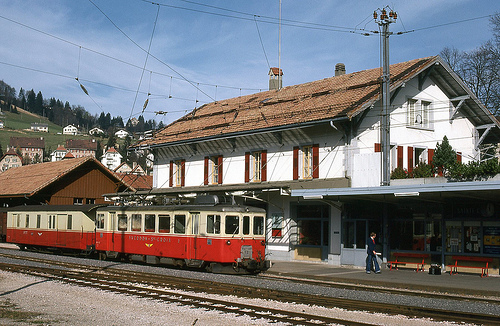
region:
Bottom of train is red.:
[82, 222, 287, 324]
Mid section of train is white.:
[25, 205, 229, 233]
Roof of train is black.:
[68, 200, 260, 223]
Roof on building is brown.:
[224, 88, 354, 154]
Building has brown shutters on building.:
[156, 157, 376, 209]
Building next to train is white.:
[335, 107, 413, 215]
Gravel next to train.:
[136, 240, 348, 312]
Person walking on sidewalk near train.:
[351, 204, 406, 306]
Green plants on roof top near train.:
[402, 110, 491, 151]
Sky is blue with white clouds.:
[126, 27, 281, 68]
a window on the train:
[172, 212, 187, 234]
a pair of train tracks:
[0, 250, 498, 324]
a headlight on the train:
[223, 235, 234, 248]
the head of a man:
[366, 228, 383, 241]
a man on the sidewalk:
[358, 227, 384, 277]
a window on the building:
[293, 142, 318, 178]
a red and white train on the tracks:
[3, 196, 273, 273]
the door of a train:
[182, 206, 204, 258]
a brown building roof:
[117, 52, 451, 152]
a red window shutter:
[310, 141, 320, 180]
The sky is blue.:
[2, 0, 497, 121]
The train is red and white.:
[5, 179, 272, 264]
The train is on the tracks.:
[2, 198, 280, 276]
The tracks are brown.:
[2, 232, 427, 323]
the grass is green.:
[1, 93, 136, 163]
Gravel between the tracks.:
[7, 241, 450, 324]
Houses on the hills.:
[4, 95, 138, 175]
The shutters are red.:
[160, 138, 320, 193]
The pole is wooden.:
[367, 3, 399, 188]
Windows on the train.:
[97, 202, 266, 241]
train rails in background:
[107, 262, 457, 323]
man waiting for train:
[357, 225, 418, 278]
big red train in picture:
[21, 162, 278, 279]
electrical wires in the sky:
[73, 42, 254, 111]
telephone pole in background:
[357, 12, 434, 277]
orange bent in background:
[448, 254, 498, 282]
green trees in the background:
[18, 81, 149, 142]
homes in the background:
[21, 105, 168, 180]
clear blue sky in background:
[47, 52, 315, 128]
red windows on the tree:
[199, 151, 418, 195]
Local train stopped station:
[2, 187, 298, 279]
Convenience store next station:
[397, 194, 498, 250]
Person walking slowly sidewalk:
[362, 220, 386, 280]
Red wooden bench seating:
[445, 252, 495, 277]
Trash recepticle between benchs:
[425, 251, 445, 276]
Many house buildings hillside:
[3, 92, 163, 166]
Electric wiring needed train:
[91, 137, 347, 204]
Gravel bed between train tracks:
[145, 266, 470, 320]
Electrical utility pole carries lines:
[340, 3, 410, 185]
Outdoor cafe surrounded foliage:
[380, 139, 499, 184]